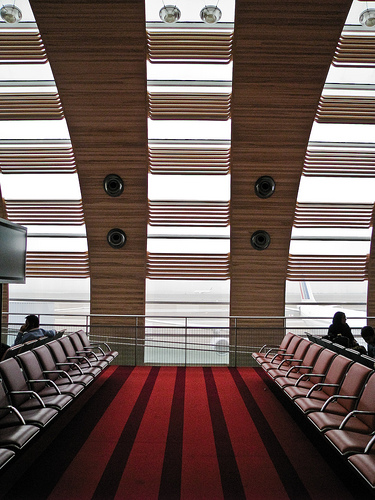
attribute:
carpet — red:
[8, 363, 364, 498]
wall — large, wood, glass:
[2, 2, 373, 364]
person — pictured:
[8, 310, 69, 351]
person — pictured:
[322, 307, 367, 354]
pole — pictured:
[183, 313, 189, 367]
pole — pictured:
[231, 311, 240, 366]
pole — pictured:
[132, 310, 140, 365]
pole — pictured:
[83, 311, 91, 337]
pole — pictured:
[281, 313, 287, 336]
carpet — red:
[42, 365, 355, 497]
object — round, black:
[254, 177, 275, 196]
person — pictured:
[325, 309, 359, 348]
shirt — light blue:
[16, 327, 63, 343]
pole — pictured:
[172, 310, 195, 365]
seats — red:
[20, 352, 119, 455]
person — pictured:
[358, 323, 374, 356]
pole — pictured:
[76, 305, 273, 345]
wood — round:
[26, 0, 149, 366]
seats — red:
[15, 359, 349, 497]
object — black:
[105, 226, 126, 250]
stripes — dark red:
[29, 358, 330, 498]